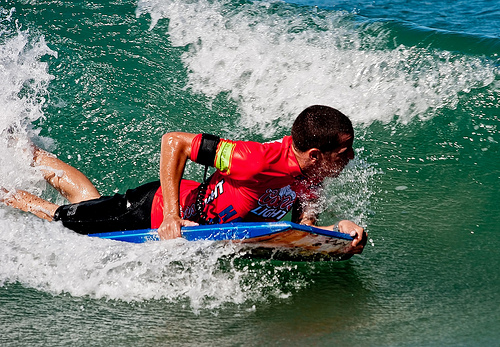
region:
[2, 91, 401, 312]
a man on a surf board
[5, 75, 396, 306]
a man laying down on a surf board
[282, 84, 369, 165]
a man with dark hair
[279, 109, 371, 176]
a man with short hair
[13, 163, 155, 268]
a man wearing black shorts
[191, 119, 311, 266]
a man wearing a red shirt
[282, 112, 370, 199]
a man with his head turned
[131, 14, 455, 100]
a white wave in the water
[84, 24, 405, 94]
a white wave in the ocean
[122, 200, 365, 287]
a man holding on to a surf board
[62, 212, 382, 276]
board in the water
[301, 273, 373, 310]
ripple in the water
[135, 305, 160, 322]
ripple in the water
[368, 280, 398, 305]
ripple in the water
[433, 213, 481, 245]
ripple in the water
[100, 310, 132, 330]
ripple in the water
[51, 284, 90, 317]
ripple in the water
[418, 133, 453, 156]
ripple in the water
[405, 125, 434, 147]
ripple in the water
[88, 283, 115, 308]
ripple in the water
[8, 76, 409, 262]
man on a surfboard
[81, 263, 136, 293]
wave in the ocean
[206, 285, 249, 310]
wave in the ocean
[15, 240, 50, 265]
wave in the ocean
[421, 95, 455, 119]
wave in the ocean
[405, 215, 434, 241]
wave in the ocean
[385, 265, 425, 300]
wave in the ocean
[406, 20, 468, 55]
wave in the ocean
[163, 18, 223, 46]
wave in the ocean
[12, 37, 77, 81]
wave in the ocean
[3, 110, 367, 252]
a man is surfing on the ocean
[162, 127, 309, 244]
the man is wearing a short sleeve shirt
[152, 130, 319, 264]
the shirt is red in color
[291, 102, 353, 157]
the man has a short hair cut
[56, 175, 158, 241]
the man is wearing shorts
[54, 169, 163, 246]
the shorts are black in color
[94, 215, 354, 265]
the surfboard is riding a wave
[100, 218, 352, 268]
the surfboard is blue in color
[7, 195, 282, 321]
water is splashing besides the surfboard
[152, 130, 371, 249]
the man is holding on to the surfboard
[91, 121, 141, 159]
ripples in ocean water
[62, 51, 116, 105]
ripples in ocean water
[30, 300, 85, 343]
ripples in ocean water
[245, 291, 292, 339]
ripples in ocean water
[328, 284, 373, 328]
ripples in ocean water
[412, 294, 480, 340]
ripples in ocean water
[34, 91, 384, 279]
man riding on boogie board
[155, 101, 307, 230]
man wearing a red shirt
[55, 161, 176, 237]
man wearing black shorts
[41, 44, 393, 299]
man riding the wave on boogie board